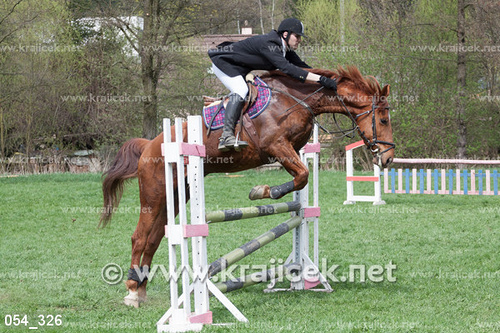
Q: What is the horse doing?
A: Jumping.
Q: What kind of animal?
A: Horse.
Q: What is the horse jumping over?
A: A jump made with green and purple poles.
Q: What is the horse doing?
A: He is going over a jump.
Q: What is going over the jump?
A: A horse and his jockey.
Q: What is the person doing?
A: Riding a brown horse.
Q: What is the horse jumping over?
A: Some poles.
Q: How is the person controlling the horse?
A: With black reins he is holding.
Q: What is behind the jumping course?
A: Trees are along the jumping course.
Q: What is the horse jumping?
A: Poles.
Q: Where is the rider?
A: On horse.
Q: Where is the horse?
A: Obsticale course.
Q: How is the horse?
A: In air.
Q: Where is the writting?
A: On photo.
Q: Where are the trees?
A: Background.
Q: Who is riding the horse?
A: A man.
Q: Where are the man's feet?
A: Stirrups.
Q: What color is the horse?
A: Brown.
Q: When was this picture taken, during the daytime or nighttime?
A: Daytime.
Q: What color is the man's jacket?
A: Black.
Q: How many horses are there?
A: One.